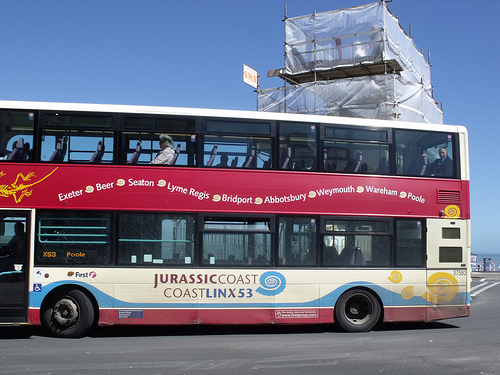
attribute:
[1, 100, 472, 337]
bus — two levelled, double decker, two stories, double decket, pink, white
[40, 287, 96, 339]
wheel — slightly turned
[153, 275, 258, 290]
words — red, purple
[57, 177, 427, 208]
words — white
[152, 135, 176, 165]
woman — sitting, seated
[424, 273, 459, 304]
sign — yellow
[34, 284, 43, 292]
handicap sign — blue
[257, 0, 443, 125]
structure — tall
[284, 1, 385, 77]
in plastic — white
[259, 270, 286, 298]
swirl design — blue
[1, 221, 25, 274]
driver — sitting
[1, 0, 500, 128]
day — clear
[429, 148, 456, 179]
person — sitting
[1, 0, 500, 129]
sky — blue, clear, cloud free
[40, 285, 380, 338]
tires — black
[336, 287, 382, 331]
tire — round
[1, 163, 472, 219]
sign — red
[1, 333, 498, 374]
ground — grey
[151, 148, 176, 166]
shirt — white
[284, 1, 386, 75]
tarp — white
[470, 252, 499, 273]
glimps — small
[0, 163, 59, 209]
animal skeleton — yellow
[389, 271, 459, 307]
abstract shells — yellow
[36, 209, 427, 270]
windows — passenger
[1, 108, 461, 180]
windows — passenger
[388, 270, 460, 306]
graphics — yellow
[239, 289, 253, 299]
number — 53